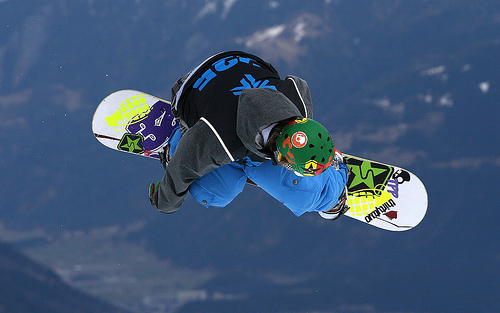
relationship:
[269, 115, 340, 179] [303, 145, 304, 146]
helmet with stickers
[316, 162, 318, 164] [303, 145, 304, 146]
green helmet stickers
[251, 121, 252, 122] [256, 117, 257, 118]
man doing stunt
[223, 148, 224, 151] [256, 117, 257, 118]
doing a stunt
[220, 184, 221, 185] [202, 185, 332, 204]
bright snow pants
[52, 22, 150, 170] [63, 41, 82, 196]
blurry mountain scenery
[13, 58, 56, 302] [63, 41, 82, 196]
slightly blurry scenery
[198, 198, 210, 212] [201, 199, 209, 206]
small metal small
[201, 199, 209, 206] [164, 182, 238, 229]
small on snowpants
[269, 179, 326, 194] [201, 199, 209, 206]
metal on small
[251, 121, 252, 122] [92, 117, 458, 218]
man riding board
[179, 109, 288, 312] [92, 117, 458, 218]
riding snow board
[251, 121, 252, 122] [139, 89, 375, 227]
man wearing jacket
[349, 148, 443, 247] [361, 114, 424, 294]
snow board colorful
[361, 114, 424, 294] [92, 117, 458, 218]
colorful snow board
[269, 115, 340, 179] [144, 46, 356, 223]
helmet on man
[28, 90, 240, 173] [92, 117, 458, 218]
white snow board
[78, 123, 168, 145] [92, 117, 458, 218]
decorations on board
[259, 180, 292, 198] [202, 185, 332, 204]
blue snow pants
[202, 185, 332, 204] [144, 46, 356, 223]
pants on man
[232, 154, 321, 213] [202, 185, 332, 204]
baby blue pants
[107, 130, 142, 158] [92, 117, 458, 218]
star on board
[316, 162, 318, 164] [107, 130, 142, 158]
green on star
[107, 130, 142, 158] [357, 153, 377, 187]
star with s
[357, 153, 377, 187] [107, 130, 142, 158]
s in star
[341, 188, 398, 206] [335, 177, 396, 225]
stencil of grenade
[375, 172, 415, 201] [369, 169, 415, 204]
letters say tpp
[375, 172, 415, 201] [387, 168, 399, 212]
letters tpp purple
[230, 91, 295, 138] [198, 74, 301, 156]
gray dark hood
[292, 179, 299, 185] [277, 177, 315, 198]
metal on button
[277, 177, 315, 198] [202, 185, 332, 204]
button on pants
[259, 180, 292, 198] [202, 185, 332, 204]
blue on pants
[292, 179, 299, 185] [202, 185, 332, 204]
metal on pants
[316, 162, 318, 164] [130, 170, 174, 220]
green part glove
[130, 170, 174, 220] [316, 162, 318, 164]
glove part green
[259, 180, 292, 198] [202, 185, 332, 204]
blue in pants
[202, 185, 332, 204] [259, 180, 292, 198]
pants in blue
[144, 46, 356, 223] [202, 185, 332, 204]
man in pants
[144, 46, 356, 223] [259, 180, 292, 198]
man in blue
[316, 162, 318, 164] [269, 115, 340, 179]
green on helmet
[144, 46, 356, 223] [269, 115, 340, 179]
man green helmet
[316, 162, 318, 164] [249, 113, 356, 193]
green on helmet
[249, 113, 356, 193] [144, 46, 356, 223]
helmet on man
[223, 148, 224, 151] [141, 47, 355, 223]
doing a stunt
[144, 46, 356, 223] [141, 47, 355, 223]
man in stunt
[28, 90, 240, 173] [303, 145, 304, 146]
white snowboard stickers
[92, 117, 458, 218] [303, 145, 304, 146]
snowboard with stickers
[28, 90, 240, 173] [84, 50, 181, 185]
white with stickers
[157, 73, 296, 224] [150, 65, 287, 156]
hoodies with vest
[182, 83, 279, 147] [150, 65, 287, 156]
grey black vest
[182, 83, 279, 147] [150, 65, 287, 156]
grey with vest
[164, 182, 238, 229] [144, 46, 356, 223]
snowpants on man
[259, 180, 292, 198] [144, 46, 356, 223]
blue on man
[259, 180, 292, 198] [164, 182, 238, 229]
blue on snowpants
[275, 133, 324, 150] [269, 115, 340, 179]
sticker on helmet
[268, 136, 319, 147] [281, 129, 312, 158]
red on helmit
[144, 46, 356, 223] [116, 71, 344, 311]
man in air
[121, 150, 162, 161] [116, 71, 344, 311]
flying in air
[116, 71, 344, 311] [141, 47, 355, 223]
person doing stunt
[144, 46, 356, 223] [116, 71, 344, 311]
man in person